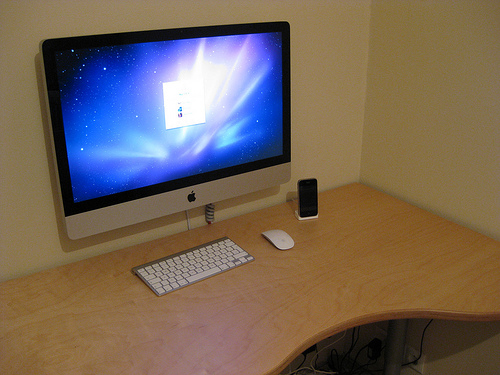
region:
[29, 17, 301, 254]
a computer is fixed on a wall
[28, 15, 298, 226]
screen of computer is blue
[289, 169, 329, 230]
speaker of computer on a desk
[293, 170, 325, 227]
speaker is black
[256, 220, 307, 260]
mouse is white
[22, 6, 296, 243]
computer brand is apple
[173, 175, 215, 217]
logotype of computer is black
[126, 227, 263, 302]
a white keyboard on a desk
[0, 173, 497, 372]
a brown desk under a computer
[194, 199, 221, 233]
a wire is seen behind computer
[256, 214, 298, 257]
white mouse on a desk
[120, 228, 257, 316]
keyboard on a desk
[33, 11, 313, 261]
computer on the wall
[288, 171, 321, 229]
cellphone in a dock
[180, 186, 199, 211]
logo on a computer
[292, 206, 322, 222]
cell phone dock on a desk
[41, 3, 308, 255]
a large computer on the wall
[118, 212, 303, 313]
keyboard and mouse on a desk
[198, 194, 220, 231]
cord on a computer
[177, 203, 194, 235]
cord to a computer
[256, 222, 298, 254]
white mac mouse on desk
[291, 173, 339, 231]
ipod on dock on desk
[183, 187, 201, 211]
apple logo on computer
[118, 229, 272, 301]
keyboard on top of desk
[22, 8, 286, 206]
large imac computer screen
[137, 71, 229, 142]
message on computer screen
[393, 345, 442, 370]
beige outlet on wall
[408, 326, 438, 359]
black cord on wall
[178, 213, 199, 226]
grey cord on wall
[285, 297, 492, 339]
inside curve of wood desk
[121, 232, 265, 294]
portable white computer keyboard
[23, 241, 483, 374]
computer desk with computer on it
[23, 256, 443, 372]
desk is made of wood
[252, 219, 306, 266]
the mouse is white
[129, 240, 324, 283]
the keyboard is white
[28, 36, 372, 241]
computer is an apple product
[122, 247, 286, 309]
keyboard is very small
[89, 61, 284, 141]
blue screen on computer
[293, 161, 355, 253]
the speaker is black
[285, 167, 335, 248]
speaker sitting on the desk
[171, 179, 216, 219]
apple sign is black